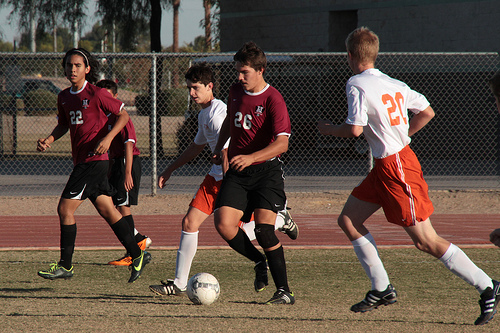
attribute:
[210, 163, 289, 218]
shorts — black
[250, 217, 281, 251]
knee brace — black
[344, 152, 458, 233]
shorts — orange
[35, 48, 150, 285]
four kids — playing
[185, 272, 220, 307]
ball — gray and white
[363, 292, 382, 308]
lines — white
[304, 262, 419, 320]
shoe — black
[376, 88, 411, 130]
number — 20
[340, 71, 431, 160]
shirt — red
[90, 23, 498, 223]
fence — chain link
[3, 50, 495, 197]
fence — metal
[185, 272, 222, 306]
soccer ball — white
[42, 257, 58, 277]
laces — green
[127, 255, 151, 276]
swoosh — green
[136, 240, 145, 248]
shoes — orange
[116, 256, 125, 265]
shoes — orange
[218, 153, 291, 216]
shorts — black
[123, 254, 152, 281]
shoe — black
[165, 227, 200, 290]
sock — white, high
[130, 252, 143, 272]
nike check — green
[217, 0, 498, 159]
building — gray, brick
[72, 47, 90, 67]
band — white